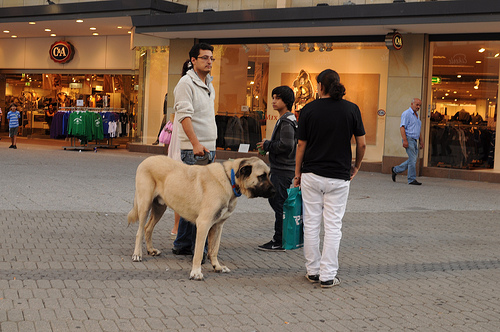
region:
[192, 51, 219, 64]
glasses on a man's face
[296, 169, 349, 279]
white pants on a person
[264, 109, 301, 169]
a grey jacket on a kid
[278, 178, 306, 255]
a blue bag in a person's hand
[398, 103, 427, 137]
a blue shirt on a man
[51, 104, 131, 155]
a clothes rack outside of a store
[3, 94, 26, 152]
a boy in a striped shirt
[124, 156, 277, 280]
a large dog by a man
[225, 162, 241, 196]
a blue collar on a dog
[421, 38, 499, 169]
a large store window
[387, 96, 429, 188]
Older man walking alone on sidewalk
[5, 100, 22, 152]
Young boy in striped blue and white polo shirt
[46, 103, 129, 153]
Outdoor sales rack with sweatshirts displayed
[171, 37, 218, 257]
Man with glasses holding the leash of a dog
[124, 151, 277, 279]
A large breed dog with a beige coat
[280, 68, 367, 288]
Woman holding a shopping bag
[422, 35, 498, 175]
display window of a clothing store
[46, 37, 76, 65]
Store sign for C&A fashion retailer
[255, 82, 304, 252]
A dark haired boy with a green object in his hands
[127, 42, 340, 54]
Outdoor lights shining on the middle display window of store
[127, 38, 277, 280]
a man walking a dog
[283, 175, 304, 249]
a woman holding a plastic green bag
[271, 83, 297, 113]
boy with a black wool hat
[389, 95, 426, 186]
an old man walking on the pavement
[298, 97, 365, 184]
a woman wearing a black shirt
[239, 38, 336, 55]
small spotlights on a shop window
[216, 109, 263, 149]
a rack of clothes in a shop window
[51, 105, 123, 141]
a rack of colorful shirts on the pavement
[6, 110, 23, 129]
boy wearing a white and blue strip shirt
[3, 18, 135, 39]
white light fixtures on the ceiling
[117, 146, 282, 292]
large dog standing on the sidewalk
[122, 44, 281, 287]
man holding onto the dog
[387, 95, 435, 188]
man walking on the sidewalk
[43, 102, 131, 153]
merchandise on the sidewalk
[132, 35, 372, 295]
group of people on the sidewalk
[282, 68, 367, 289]
woman holding a bag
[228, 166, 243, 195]
blue collar around the neck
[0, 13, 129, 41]
several lights on top of the building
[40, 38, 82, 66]
black, white, and red sign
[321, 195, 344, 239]
wrinkles in the pants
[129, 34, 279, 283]
A man is holding a leash with a very large dog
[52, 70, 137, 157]
Some racks of clothing are displayed outside the entrance of the store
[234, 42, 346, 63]
Overhead spotlights for the store window displays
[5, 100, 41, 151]
A man with a blue and white striped shirt is standing in front of the store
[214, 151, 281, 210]
The dog is wearing a blue collar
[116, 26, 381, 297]
A group of people are standing together in the common area of the mall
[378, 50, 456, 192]
An elderly man is walking past a store window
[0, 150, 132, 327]
The floor is different shapes and shades of grey concrete or cobblestone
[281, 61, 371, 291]
Guy with ponytail is holding a turquoise shopping bag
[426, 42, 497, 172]
Large store window with merchandise displayed